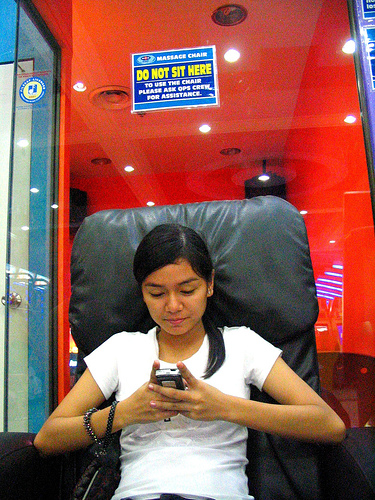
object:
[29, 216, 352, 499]
woman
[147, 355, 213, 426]
hands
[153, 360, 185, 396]
cellphone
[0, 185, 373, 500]
chair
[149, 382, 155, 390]
fingernails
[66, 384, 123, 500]
handbag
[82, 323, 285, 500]
shirt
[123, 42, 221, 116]
sign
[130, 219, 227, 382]
hair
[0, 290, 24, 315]
doorknob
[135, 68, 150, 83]
do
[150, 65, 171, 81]
not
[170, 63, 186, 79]
sit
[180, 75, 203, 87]
chair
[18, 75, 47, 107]
sticker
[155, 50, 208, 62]
massage chair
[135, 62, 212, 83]
do not sit here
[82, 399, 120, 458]
cord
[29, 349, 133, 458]
arm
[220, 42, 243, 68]
can light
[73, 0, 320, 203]
ceiling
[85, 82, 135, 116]
air vent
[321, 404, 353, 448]
elbow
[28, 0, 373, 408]
walls